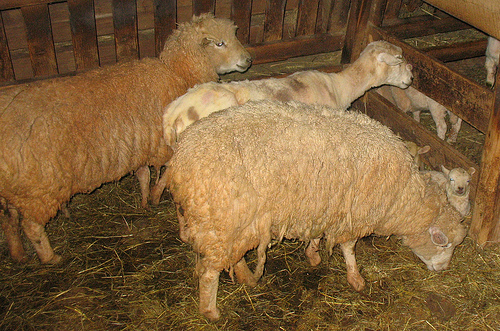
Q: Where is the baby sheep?
A: On the ground.